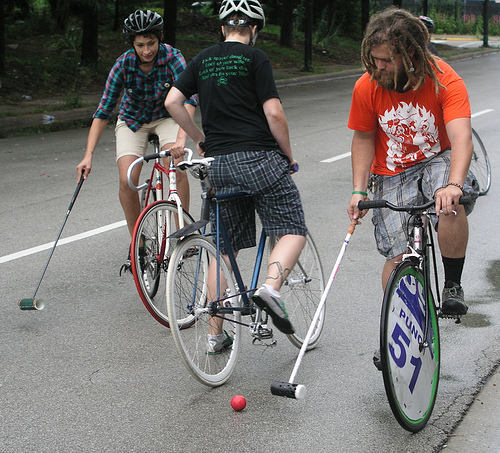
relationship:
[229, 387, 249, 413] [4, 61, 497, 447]
ball on pavement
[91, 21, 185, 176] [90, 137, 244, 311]
woman on bike